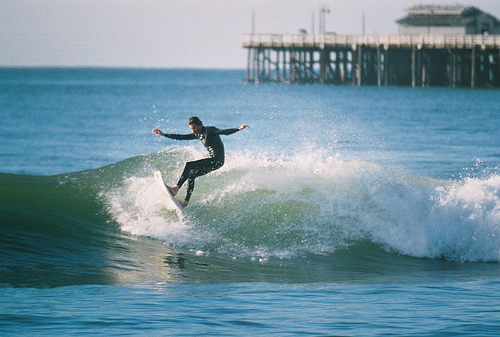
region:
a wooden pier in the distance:
[243, 47, 498, 87]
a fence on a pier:
[246, 31, 498, 45]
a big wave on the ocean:
[60, 147, 498, 264]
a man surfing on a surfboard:
[151, 115, 251, 225]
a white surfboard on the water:
[153, 166, 187, 221]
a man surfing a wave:
[152, 117, 251, 207]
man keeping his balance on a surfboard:
[153, 116, 250, 221]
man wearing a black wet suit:
[167, 125, 238, 198]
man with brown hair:
[187, 115, 201, 134]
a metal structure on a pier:
[396, 6, 496, 33]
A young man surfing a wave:
[130, 105, 263, 246]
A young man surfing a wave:
[135, 110, 260, 238]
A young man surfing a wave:
[140, 111, 262, 233]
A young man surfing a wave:
[139, 110, 266, 233]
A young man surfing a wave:
[140, 110, 258, 238]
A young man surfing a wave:
[143, 109, 253, 226]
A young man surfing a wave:
[141, 110, 253, 235]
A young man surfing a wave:
[146, 111, 256, 236]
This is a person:
[128, 103, 280, 213]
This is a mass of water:
[81, 248, 256, 335]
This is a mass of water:
[275, 140, 380, 222]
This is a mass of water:
[32, 150, 127, 240]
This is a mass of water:
[307, 115, 402, 200]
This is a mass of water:
[20, 56, 110, 136]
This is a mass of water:
[323, 235, 453, 305]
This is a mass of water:
[17, 155, 93, 266]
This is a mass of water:
[280, 78, 424, 212]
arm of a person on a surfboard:
[209, 119, 254, 137]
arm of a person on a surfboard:
[145, 122, 200, 142]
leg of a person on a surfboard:
[165, 151, 219, 196]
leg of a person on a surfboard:
[177, 163, 217, 208]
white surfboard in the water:
[155, 162, 184, 220]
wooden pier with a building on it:
[236, 2, 498, 97]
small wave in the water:
[3, 146, 498, 275]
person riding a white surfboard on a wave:
[139, 112, 257, 230]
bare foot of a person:
[163, 183, 182, 196]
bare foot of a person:
[172, 195, 193, 210]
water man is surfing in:
[4, 79, 486, 318]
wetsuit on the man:
[160, 130, 238, 179]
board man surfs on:
[150, 164, 189, 228]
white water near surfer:
[173, 143, 480, 242]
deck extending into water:
[231, 22, 499, 94]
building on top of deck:
[391, 6, 498, 43]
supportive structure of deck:
[241, 55, 498, 88]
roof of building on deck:
[408, 4, 487, 18]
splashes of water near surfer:
[138, 105, 171, 131]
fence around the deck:
[233, 30, 495, 48]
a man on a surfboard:
[150, 115, 251, 219]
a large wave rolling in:
[0, 144, 498, 286]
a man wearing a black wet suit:
[152, 115, 248, 205]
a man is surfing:
[152, 116, 243, 201]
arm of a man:
[216, 123, 248, 135]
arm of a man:
[154, 124, 194, 139]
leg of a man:
[181, 158, 219, 200]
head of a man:
[187, 116, 202, 133]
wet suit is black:
[162, 129, 242, 196]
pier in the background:
[245, 31, 498, 90]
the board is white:
[150, 168, 195, 222]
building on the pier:
[395, 8, 495, 41]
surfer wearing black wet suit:
[152, 113, 251, 205]